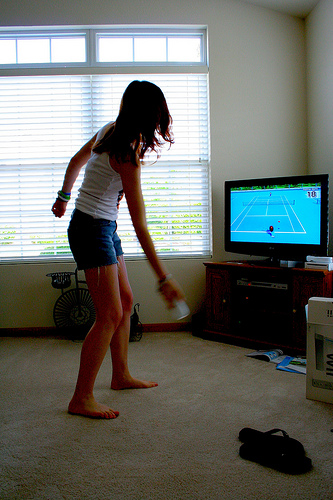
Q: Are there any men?
A: No, there are no men.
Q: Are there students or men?
A: No, there are no men or students.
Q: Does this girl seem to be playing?
A: Yes, the girl is playing.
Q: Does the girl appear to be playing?
A: Yes, the girl is playing.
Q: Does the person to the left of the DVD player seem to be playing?
A: Yes, the girl is playing.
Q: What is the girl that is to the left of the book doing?
A: The girl is playing.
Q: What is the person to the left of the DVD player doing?
A: The girl is playing.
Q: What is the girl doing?
A: The girl is playing.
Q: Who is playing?
A: The girl is playing.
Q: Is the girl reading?
A: No, the girl is playing.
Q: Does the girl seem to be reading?
A: No, the girl is playing.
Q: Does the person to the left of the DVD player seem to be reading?
A: No, the girl is playing.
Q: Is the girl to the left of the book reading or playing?
A: The girl is playing.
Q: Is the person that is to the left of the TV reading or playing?
A: The girl is playing.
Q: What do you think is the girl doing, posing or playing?
A: The girl is playing.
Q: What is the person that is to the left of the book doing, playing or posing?
A: The girl is playing.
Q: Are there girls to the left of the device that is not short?
A: Yes, there is a girl to the left of the DVD player.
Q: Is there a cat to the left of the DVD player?
A: No, there is a girl to the left of the DVD player.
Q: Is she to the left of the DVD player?
A: Yes, the girl is to the left of the DVD player.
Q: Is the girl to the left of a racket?
A: No, the girl is to the left of the DVD player.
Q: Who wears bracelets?
A: The girl wears bracelets.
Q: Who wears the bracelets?
A: The girl wears bracelets.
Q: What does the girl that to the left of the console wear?
A: The girl wears bracelets.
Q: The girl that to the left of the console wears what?
A: The girl wears bracelets.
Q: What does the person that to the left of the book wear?
A: The girl wears bracelets.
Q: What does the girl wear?
A: The girl wears bracelets.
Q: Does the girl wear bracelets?
A: Yes, the girl wears bracelets.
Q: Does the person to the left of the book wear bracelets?
A: Yes, the girl wears bracelets.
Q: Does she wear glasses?
A: No, the girl wears bracelets.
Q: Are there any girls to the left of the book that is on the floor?
A: Yes, there is a girl to the left of the book.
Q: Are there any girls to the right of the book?
A: No, the girl is to the left of the book.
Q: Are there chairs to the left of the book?
A: No, there is a girl to the left of the book.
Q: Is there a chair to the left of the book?
A: No, there is a girl to the left of the book.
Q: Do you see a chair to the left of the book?
A: No, there is a girl to the left of the book.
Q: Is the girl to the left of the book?
A: Yes, the girl is to the left of the book.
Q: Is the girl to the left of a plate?
A: No, the girl is to the left of the book.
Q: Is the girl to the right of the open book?
A: No, the girl is to the left of the book.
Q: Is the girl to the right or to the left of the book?
A: The girl is to the left of the book.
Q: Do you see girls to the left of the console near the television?
A: Yes, there is a girl to the left of the console.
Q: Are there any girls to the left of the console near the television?
A: Yes, there is a girl to the left of the console.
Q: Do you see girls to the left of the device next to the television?
A: Yes, there is a girl to the left of the console.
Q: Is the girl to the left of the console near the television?
A: Yes, the girl is to the left of the console.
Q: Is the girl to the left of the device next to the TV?
A: Yes, the girl is to the left of the console.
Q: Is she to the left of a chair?
A: No, the girl is to the left of the console.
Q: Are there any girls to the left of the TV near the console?
A: Yes, there is a girl to the left of the television.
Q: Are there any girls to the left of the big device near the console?
A: Yes, there is a girl to the left of the television.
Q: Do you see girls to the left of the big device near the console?
A: Yes, there is a girl to the left of the television.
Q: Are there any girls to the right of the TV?
A: No, the girl is to the left of the TV.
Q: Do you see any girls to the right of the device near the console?
A: No, the girl is to the left of the TV.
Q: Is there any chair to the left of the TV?
A: No, there is a girl to the left of the TV.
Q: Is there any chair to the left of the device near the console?
A: No, there is a girl to the left of the TV.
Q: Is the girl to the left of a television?
A: Yes, the girl is to the left of a television.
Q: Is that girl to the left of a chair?
A: No, the girl is to the left of a television.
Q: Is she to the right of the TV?
A: No, the girl is to the left of the TV.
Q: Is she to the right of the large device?
A: No, the girl is to the left of the TV.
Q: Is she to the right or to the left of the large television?
A: The girl is to the left of the TV.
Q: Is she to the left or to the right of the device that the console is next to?
A: The girl is to the left of the TV.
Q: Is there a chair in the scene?
A: No, there are no chairs.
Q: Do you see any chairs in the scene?
A: No, there are no chairs.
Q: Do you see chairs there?
A: No, there are no chairs.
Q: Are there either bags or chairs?
A: No, there are no chairs or bags.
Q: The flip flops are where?
A: The flip flops are on the floor.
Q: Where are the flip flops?
A: The flip flops are on the floor.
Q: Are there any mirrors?
A: No, there are no mirrors.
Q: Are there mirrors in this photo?
A: No, there are no mirrors.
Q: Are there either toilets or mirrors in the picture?
A: No, there are no mirrors or toilets.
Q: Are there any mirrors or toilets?
A: No, there are no mirrors or toilets.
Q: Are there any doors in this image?
A: Yes, there is a door.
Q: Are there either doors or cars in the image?
A: Yes, there is a door.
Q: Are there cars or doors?
A: Yes, there is a door.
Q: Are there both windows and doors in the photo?
A: Yes, there are both a door and windows.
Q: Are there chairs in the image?
A: No, there are no chairs.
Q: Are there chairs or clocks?
A: No, there are no chairs or clocks.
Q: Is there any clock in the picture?
A: No, there are no clocks.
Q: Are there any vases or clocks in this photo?
A: No, there are no clocks or vases.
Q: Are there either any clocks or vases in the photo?
A: No, there are no clocks or vases.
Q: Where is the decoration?
A: The decoration is on the floor.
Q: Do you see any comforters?
A: No, there are no comforters.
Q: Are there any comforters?
A: No, there are no comforters.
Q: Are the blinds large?
A: Yes, the blinds are large.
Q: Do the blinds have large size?
A: Yes, the blinds are large.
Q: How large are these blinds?
A: The blinds are large.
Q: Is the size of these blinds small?
A: No, the blinds are large.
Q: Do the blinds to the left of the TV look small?
A: No, the blinds are large.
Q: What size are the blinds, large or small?
A: The blinds are large.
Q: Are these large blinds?
A: Yes, these are large blinds.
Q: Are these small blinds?
A: No, these are large blinds.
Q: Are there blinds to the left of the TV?
A: Yes, there are blinds to the left of the TV.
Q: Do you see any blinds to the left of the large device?
A: Yes, there are blinds to the left of the TV.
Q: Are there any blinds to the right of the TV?
A: No, the blinds are to the left of the TV.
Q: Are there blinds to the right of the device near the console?
A: No, the blinds are to the left of the TV.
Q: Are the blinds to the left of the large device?
A: Yes, the blinds are to the left of the television.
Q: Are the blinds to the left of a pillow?
A: No, the blinds are to the left of the television.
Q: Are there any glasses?
A: No, there are no glasses.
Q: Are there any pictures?
A: No, there are no pictures.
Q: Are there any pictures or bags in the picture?
A: No, there are no pictures or bags.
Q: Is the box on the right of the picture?
A: Yes, the box is on the right of the image.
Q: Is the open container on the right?
A: Yes, the box is on the right of the image.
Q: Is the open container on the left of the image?
A: No, the box is on the right of the image.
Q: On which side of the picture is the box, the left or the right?
A: The box is on the right of the image.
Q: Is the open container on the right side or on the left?
A: The box is on the right of the image.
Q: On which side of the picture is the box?
A: The box is on the right of the image.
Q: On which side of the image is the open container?
A: The box is on the right of the image.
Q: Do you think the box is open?
A: Yes, the box is open.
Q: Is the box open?
A: Yes, the box is open.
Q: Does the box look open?
A: Yes, the box is open.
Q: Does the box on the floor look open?
A: Yes, the box is open.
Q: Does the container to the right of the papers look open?
A: Yes, the box is open.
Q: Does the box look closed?
A: No, the box is open.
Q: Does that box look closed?
A: No, the box is open.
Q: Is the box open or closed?
A: The box is open.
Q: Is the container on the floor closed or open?
A: The box is open.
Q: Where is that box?
A: The box is on the floor.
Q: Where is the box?
A: The box is on the floor.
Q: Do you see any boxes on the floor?
A: Yes, there is a box on the floor.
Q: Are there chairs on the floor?
A: No, there is a box on the floor.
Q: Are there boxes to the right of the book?
A: Yes, there is a box to the right of the book.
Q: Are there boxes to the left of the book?
A: No, the box is to the right of the book.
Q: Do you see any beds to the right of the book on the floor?
A: No, there is a box to the right of the book.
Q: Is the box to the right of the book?
A: Yes, the box is to the right of the book.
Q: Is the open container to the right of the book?
A: Yes, the box is to the right of the book.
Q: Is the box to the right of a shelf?
A: No, the box is to the right of the book.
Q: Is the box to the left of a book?
A: No, the box is to the right of a book.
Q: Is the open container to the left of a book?
A: No, the box is to the right of a book.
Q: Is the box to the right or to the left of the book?
A: The box is to the right of the book.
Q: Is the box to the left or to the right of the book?
A: The box is to the right of the book.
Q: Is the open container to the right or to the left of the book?
A: The box is to the right of the book.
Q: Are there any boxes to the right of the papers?
A: Yes, there is a box to the right of the papers.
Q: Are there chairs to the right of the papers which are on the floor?
A: No, there is a box to the right of the papers.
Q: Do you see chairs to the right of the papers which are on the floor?
A: No, there is a box to the right of the papers.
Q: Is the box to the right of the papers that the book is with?
A: Yes, the box is to the right of the papers.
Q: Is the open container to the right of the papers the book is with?
A: Yes, the box is to the right of the papers.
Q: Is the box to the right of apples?
A: No, the box is to the right of the papers.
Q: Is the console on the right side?
A: Yes, the console is on the right of the image.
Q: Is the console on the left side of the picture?
A: No, the console is on the right of the image.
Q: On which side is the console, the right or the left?
A: The console is on the right of the image.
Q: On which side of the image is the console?
A: The console is on the right of the image.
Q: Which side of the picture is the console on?
A: The console is on the right of the image.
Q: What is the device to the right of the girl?
A: The device is a console.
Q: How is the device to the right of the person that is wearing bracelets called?
A: The device is a console.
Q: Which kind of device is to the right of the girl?
A: The device is a console.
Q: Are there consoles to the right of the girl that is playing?
A: Yes, there is a console to the right of the girl.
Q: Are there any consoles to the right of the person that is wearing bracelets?
A: Yes, there is a console to the right of the girl.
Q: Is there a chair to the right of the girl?
A: No, there is a console to the right of the girl.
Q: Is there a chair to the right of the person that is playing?
A: No, there is a console to the right of the girl.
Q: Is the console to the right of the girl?
A: Yes, the console is to the right of the girl.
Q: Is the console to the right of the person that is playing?
A: Yes, the console is to the right of the girl.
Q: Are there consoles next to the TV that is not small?
A: Yes, there is a console next to the TV.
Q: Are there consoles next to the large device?
A: Yes, there is a console next to the TV.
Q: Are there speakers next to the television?
A: No, there is a console next to the television.